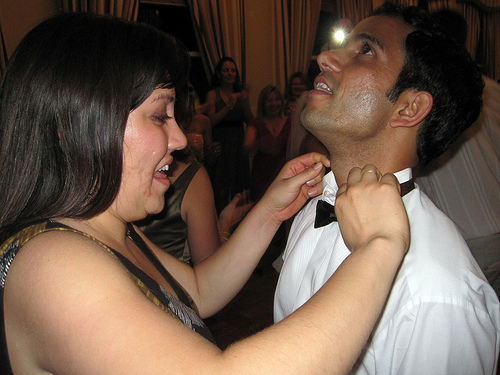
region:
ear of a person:
[383, 86, 436, 130]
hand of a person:
[327, 161, 416, 252]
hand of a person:
[261, 139, 339, 226]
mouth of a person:
[145, 153, 177, 190]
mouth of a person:
[307, 70, 333, 102]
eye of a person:
[149, 105, 171, 128]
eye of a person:
[357, 42, 380, 59]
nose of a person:
[314, 45, 345, 72]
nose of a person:
[160, 122, 193, 152]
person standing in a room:
[203, 53, 249, 161]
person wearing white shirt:
[242, 13, 498, 374]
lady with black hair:
[0, 13, 408, 371]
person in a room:
[200, 53, 257, 150]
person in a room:
[239, 80, 294, 173]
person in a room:
[282, 68, 316, 101]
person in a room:
[252, 3, 494, 374]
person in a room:
[0, 12, 414, 374]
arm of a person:
[131, 147, 340, 319]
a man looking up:
[274, 7, 496, 373]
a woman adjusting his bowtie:
[2, 9, 409, 367]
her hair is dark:
[0, 9, 187, 223]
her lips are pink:
[149, 158, 174, 193]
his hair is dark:
[375, 0, 487, 180]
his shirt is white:
[280, 170, 492, 372]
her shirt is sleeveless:
[2, 198, 231, 371]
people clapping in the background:
[185, 46, 323, 215]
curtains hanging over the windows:
[64, 0, 496, 93]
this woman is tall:
[205, 55, 257, 207]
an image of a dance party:
[6, 0, 498, 372]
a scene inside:
[6, 6, 485, 361]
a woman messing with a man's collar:
[2, 13, 396, 373]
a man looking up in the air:
[257, 0, 497, 372]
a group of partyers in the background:
[127, 44, 339, 319]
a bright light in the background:
[316, 17, 371, 64]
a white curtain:
[182, 4, 326, 125]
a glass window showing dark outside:
[118, 0, 220, 103]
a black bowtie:
[311, 173, 424, 234]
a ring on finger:
[355, 160, 386, 192]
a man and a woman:
[7, 4, 488, 374]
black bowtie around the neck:
[301, 175, 431, 240]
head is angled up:
[293, 8, 472, 186]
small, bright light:
[332, 25, 350, 46]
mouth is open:
[150, 156, 176, 188]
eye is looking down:
[149, 103, 176, 129]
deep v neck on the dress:
[250, 111, 289, 204]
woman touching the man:
[4, 1, 482, 374]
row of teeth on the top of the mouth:
[309, 76, 334, 96]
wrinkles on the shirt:
[464, 298, 495, 364]